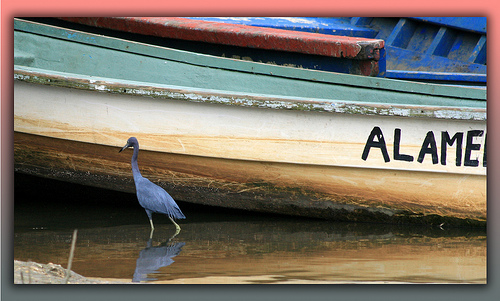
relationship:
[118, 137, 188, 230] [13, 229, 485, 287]
bird standing in water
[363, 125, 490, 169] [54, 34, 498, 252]
name appears on boat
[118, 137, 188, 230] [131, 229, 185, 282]
bird has reflection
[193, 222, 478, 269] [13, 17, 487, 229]
water under boat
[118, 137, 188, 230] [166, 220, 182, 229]
bird has leg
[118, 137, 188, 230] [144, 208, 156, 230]
bird has bird legs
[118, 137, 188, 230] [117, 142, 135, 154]
bird has beak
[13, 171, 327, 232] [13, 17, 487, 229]
shadow under boat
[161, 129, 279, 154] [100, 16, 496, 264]
water stain on boat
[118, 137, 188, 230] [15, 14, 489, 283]
bird on photo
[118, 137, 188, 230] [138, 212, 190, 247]
bird has bird legs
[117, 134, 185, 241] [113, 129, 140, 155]
bird has head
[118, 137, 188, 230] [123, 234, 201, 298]
bird has reflection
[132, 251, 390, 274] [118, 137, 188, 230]
water next bird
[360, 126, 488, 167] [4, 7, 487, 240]
name on boat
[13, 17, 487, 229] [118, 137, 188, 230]
boat next bird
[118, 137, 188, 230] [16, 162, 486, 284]
bird on water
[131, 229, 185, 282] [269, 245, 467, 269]
reflection on water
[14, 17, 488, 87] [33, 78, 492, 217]
blue boat behind boat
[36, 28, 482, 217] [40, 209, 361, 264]
boat in water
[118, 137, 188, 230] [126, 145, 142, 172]
bird has neck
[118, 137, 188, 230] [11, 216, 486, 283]
bird in water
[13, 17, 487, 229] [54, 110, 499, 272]
boat in water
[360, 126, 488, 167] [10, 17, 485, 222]
name on side of canoe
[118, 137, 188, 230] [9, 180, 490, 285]
bird in water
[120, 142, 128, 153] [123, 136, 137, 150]
beak in face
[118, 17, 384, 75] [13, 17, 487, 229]
rust on boat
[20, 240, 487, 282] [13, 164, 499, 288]
water in river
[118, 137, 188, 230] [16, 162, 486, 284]
bird in water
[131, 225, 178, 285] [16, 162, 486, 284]
reflection in water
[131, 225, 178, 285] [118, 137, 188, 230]
reflection from bird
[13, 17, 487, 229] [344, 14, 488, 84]
boat has edge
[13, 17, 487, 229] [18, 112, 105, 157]
boat has rust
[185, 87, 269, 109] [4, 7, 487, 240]
crackled paint on boat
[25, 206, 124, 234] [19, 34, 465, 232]
shadow under boat